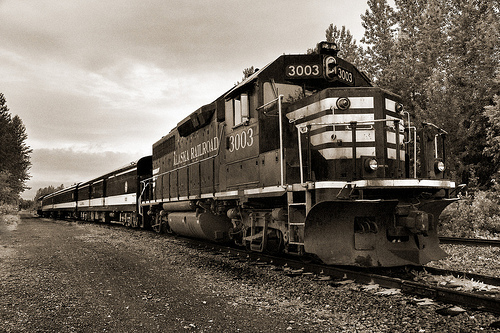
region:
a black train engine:
[146, 44, 451, 273]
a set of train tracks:
[354, 259, 498, 315]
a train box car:
[102, 158, 144, 226]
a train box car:
[87, 170, 105, 221]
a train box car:
[75, 177, 87, 220]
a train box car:
[59, 183, 76, 215]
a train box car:
[40, 191, 55, 215]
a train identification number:
[286, 60, 318, 77]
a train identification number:
[335, 65, 356, 85]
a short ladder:
[287, 194, 308, 245]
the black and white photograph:
[16, 7, 492, 325]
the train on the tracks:
[22, 32, 447, 283]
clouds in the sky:
[89, 6, 240, 53]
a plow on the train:
[285, 193, 478, 276]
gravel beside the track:
[246, 272, 328, 326]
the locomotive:
[138, 25, 482, 269]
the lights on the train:
[327, 135, 473, 185]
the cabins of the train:
[25, 143, 147, 223]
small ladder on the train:
[280, 182, 315, 249]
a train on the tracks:
[39, 46, 454, 266]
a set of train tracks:
[187, 238, 497, 328]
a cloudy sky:
[2, 4, 373, 180]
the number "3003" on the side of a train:
[227, 128, 255, 150]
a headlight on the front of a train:
[362, 158, 378, 171]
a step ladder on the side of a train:
[283, 186, 305, 254]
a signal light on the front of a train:
[328, 54, 339, 76]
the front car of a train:
[148, 50, 445, 261]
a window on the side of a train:
[228, 95, 248, 126]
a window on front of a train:
[261, 78, 304, 107]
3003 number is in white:
[274, 55, 316, 79]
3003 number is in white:
[337, 66, 362, 86]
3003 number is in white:
[226, 132, 265, 151]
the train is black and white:
[145, 62, 463, 274]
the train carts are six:
[27, 160, 142, 222]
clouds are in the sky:
[43, 34, 185, 131]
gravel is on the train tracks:
[218, 263, 308, 332]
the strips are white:
[306, 84, 414, 168]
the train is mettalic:
[158, 92, 448, 307]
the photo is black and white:
[1, 5, 495, 327]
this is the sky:
[51, 24, 173, 79]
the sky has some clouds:
[90, 15, 162, 46]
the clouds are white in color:
[71, 15, 193, 78]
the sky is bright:
[25, 12, 85, 65]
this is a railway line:
[386, 265, 498, 296]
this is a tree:
[373, 6, 493, 72]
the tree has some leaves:
[386, 11, 492, 89]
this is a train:
[33, 44, 450, 289]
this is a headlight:
[318, 50, 338, 76]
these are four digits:
[228, 130, 258, 152]